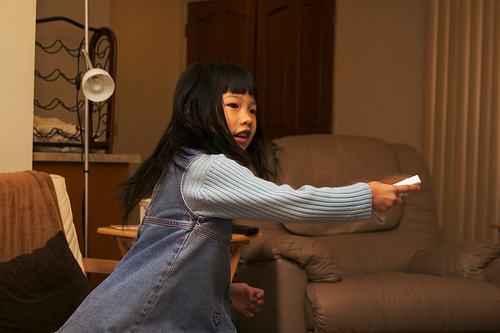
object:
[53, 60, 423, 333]
girl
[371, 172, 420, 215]
wii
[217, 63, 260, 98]
bangs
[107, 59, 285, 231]
hair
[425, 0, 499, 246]
curtains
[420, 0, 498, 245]
window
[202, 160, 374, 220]
arm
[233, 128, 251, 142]
mouth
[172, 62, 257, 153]
head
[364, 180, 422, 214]
hand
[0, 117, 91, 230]
pillow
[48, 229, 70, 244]
corner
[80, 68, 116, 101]
lamp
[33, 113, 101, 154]
linen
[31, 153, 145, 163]
counter top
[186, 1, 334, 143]
doors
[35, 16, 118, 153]
wine rack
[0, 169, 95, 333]
blanket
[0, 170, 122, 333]
couch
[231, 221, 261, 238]
tv remote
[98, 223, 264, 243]
table top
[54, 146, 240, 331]
dress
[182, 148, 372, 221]
sweater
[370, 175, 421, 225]
cloth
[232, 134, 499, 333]
chair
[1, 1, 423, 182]
wall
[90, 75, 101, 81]
bulb holder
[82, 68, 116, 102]
lampshade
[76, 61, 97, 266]
shand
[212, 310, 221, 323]
badge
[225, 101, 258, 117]
these